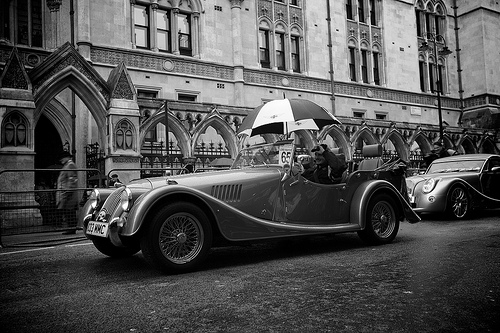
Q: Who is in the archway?
A: A man.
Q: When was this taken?
A: Daytime.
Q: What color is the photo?
A: Black and white.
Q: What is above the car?
A: Umbrella.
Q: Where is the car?
A: In front of the building.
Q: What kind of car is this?
A: Old.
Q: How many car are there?
A: Two.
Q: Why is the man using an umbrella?
A: No top on his car.